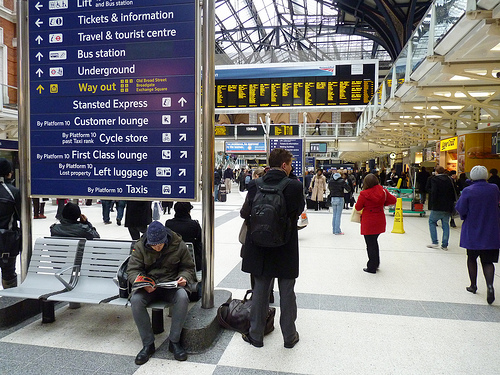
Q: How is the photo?
A: Clear.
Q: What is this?
A: Sign.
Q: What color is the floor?
A: Black and white.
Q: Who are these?
A: People.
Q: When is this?
A: Daytime.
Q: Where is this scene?
A: Bus station.